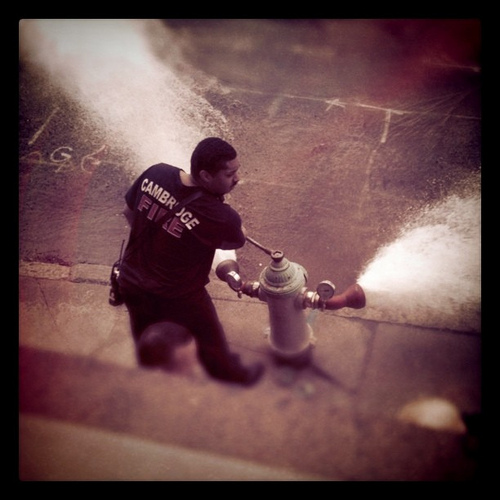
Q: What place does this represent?
A: It represents the sidewalk.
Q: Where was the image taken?
A: It was taken at the sidewalk.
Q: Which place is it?
A: It is a sidewalk.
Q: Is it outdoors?
A: Yes, it is outdoors.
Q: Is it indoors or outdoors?
A: It is outdoors.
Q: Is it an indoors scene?
A: No, it is outdoors.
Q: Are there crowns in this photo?
A: No, there are no crowns.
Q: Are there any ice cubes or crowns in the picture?
A: No, there are no crowns or ice cubes.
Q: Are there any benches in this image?
A: No, there are no benches.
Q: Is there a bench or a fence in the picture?
A: No, there are no benches or fences.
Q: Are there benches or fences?
A: No, there are no benches or fences.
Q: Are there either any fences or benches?
A: No, there are no benches or fences.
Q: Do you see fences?
A: No, there are no fences.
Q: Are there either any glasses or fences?
A: No, there are no fences or glasses.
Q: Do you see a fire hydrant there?
A: Yes, there is a fire hydrant.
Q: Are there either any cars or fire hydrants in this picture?
A: Yes, there is a fire hydrant.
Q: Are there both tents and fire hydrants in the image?
A: No, there is a fire hydrant but no tents.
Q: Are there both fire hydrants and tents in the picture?
A: No, there is a fire hydrant but no tents.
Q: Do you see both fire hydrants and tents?
A: No, there is a fire hydrant but no tents.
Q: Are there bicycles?
A: No, there are no bicycles.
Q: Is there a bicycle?
A: No, there are no bicycles.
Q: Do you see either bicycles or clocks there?
A: No, there are no bicycles or clocks.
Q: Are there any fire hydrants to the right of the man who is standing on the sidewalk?
A: Yes, there is a fire hydrant to the right of the man.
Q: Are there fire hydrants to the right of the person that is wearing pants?
A: Yes, there is a fire hydrant to the right of the man.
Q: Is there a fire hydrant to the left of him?
A: No, the fire hydrant is to the right of the man.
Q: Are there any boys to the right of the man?
A: No, there is a fire hydrant to the right of the man.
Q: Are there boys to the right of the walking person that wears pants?
A: No, there is a fire hydrant to the right of the man.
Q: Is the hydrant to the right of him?
A: Yes, the hydrant is to the right of the man.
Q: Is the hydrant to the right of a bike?
A: No, the hydrant is to the right of the man.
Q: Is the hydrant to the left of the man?
A: No, the hydrant is to the right of the man.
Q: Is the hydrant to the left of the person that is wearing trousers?
A: No, the hydrant is to the right of the man.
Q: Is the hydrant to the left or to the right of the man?
A: The hydrant is to the right of the man.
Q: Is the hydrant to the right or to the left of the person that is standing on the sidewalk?
A: The hydrant is to the right of the man.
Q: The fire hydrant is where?
A: The fire hydrant is on the street.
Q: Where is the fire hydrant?
A: The fire hydrant is on the street.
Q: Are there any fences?
A: No, there are no fences.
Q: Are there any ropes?
A: No, there are no ropes.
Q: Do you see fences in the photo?
A: No, there are no fences.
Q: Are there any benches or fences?
A: No, there are no fences or benches.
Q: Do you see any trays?
A: No, there are no trays.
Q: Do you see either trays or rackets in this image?
A: No, there are no trays or rackets.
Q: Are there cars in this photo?
A: No, there are no cars.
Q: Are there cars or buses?
A: No, there are no cars or buses.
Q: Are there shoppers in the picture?
A: No, there are no shoppers.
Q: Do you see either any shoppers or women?
A: No, there are no shoppers or women.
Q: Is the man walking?
A: Yes, the man is walking.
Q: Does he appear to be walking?
A: Yes, the man is walking.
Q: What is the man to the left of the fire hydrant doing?
A: The man is walking.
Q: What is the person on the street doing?
A: The man is walking.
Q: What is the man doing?
A: The man is walking.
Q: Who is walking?
A: The man is walking.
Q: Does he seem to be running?
A: No, the man is walking.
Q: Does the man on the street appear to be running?
A: No, the man is walking.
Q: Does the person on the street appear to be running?
A: No, the man is walking.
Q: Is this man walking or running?
A: The man is walking.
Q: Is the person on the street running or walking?
A: The man is walking.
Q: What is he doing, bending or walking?
A: The man is walking.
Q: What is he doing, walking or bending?
A: The man is walking.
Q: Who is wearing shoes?
A: The man is wearing shoes.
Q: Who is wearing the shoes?
A: The man is wearing shoes.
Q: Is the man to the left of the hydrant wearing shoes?
A: Yes, the man is wearing shoes.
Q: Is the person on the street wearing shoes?
A: Yes, the man is wearing shoes.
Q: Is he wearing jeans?
A: No, the man is wearing shoes.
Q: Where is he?
A: The man is on the street.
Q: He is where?
A: The man is on the street.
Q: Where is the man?
A: The man is on the street.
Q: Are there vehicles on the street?
A: No, there is a man on the street.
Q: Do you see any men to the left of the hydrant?
A: Yes, there is a man to the left of the hydrant.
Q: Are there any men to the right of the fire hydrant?
A: No, the man is to the left of the fire hydrant.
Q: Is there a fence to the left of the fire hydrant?
A: No, there is a man to the left of the fire hydrant.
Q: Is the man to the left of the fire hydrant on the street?
A: Yes, the man is to the left of the hydrant.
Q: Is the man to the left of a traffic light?
A: No, the man is to the left of the hydrant.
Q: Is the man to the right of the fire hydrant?
A: No, the man is to the left of the fire hydrant.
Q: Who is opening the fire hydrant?
A: The man is opening the fire hydrant.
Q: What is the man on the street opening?
A: The man is opening the fire hydrant.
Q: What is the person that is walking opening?
A: The man is opening the fire hydrant.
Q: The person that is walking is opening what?
A: The man is opening the fire hydrant.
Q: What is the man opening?
A: The man is opening the fire hydrant.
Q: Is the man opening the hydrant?
A: Yes, the man is opening the hydrant.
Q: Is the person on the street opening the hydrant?
A: Yes, the man is opening the hydrant.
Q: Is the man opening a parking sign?
A: No, the man is opening the hydrant.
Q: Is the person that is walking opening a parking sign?
A: No, the man is opening the hydrant.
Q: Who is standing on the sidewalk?
A: The man is standing on the sidewalk.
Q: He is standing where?
A: The man is standing on the sidewalk.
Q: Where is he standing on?
A: The man is standing on the sidewalk.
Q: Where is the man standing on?
A: The man is standing on the sidewalk.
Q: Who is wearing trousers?
A: The man is wearing trousers.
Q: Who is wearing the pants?
A: The man is wearing trousers.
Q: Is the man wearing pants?
A: Yes, the man is wearing pants.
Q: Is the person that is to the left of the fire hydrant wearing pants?
A: Yes, the man is wearing pants.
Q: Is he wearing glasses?
A: No, the man is wearing pants.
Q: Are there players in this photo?
A: No, there are no players.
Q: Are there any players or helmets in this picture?
A: No, there are no players or helmets.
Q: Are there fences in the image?
A: No, there are no fences.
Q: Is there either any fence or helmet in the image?
A: No, there are no fences or helmets.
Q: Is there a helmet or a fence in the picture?
A: No, there are no fences or helmets.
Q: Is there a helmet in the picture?
A: No, there are no helmets.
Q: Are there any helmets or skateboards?
A: No, there are no helmets or skateboards.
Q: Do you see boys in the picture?
A: No, there are no boys.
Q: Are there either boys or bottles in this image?
A: No, there are no boys or bottles.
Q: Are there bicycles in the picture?
A: No, there are no bicycles.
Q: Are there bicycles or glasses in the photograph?
A: No, there are no bicycles or glasses.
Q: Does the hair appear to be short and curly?
A: Yes, the hair is short and curly.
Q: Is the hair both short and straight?
A: No, the hair is short but curly.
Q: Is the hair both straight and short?
A: No, the hair is short but curly.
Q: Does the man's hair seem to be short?
A: Yes, the hair is short.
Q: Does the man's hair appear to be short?
A: Yes, the hair is short.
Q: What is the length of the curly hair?
A: The hair is short.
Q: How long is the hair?
A: The hair is short.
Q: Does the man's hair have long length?
A: No, the hair is short.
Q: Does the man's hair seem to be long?
A: No, the hair is short.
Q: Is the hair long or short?
A: The hair is short.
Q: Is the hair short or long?
A: The hair is short.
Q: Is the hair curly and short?
A: Yes, the hair is curly and short.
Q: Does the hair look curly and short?
A: Yes, the hair is curly and short.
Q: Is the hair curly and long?
A: No, the hair is curly but short.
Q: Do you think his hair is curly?
A: Yes, the hair is curly.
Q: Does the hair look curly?
A: Yes, the hair is curly.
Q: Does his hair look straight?
A: No, the hair is curly.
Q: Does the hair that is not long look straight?
A: No, the hair is curly.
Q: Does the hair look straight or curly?
A: The hair is curly.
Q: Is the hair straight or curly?
A: The hair is curly.